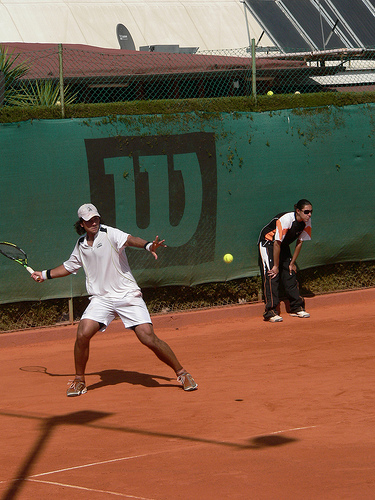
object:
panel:
[240, 3, 375, 56]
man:
[0, 201, 199, 398]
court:
[0, 283, 375, 499]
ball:
[222, 253, 235, 265]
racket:
[1, 236, 45, 285]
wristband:
[39, 264, 53, 284]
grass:
[0, 89, 374, 124]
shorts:
[79, 292, 153, 329]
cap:
[75, 201, 101, 222]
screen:
[0, 104, 374, 306]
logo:
[82, 129, 218, 270]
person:
[256, 197, 315, 323]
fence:
[0, 39, 372, 301]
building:
[2, 14, 326, 103]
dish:
[111, 19, 143, 54]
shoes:
[175, 370, 199, 392]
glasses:
[303, 207, 314, 216]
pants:
[249, 241, 311, 321]